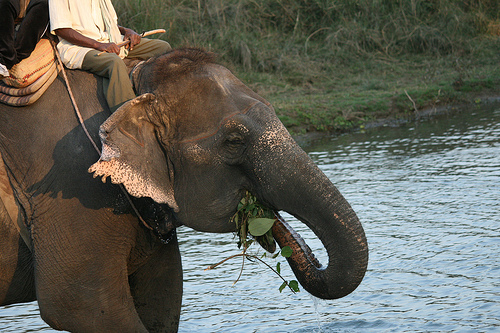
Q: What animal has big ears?
A: Elephant.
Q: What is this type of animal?
A: An elephant.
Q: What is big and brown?
A: An elephant.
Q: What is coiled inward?
A: Trunk.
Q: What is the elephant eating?
A: Leaves.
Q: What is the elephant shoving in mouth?
A: Leaves.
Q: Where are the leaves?
A: Mouth.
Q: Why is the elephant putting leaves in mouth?
A: Hungry.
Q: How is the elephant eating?
A: Using trunk.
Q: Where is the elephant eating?
A: In water.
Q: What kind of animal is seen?
A: Elephant.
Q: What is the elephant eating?
A: Plants.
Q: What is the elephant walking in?
A: Water.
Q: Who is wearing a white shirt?
A: Boy on elephant.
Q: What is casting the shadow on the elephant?
A: Ear.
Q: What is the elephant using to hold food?
A: Trunk.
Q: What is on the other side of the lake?
A: Grass.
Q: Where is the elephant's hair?
A: On top of its head.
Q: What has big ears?
A: Elephant.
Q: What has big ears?
A: The elephant.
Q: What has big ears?
A: The elephant.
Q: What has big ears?
A: The elephant.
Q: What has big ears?
A: The elephant.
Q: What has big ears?
A: The elephant.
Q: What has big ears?
A: The elephant.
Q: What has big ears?
A: The elephant.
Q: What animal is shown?
A: Elephant.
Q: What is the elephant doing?
A: Eating.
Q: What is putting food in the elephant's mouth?
A: Trunk.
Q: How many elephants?
A: 1.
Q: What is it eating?
A: Grass.